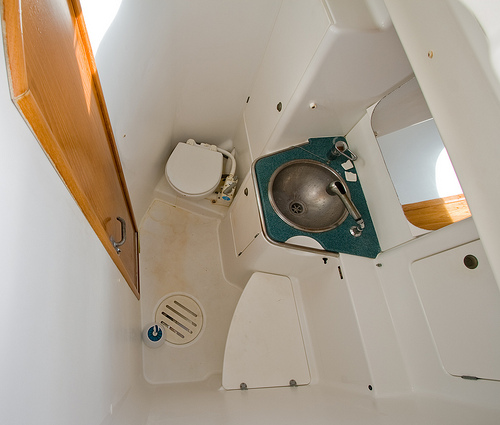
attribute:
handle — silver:
[99, 209, 127, 251]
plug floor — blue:
[134, 298, 178, 367]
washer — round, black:
[410, 238, 497, 381]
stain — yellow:
[145, 198, 192, 293]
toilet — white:
[146, 108, 265, 225]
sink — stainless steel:
[255, 132, 397, 260]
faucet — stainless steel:
[325, 180, 365, 238]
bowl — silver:
[269, 157, 359, 235]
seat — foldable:
[216, 268, 313, 389]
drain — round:
[153, 294, 204, 349]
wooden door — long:
[3, 3, 148, 306]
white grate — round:
[168, 290, 204, 331]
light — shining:
[79, 0, 133, 69]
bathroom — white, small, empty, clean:
[116, 121, 381, 293]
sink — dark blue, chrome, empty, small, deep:
[253, 136, 380, 263]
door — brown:
[3, 55, 140, 212]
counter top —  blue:
[255, 134, 380, 257]